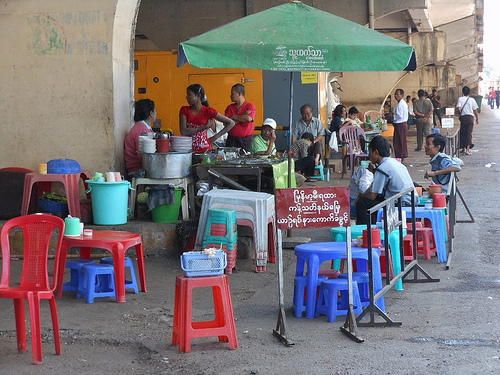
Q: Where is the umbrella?
A: On the sidewalk.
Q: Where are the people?
A: At the restaurant.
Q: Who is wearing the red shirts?
A: The wait staff.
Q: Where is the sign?
A: Next to the buildings.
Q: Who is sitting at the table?
A: Two men.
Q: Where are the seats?
A: On the sidewalk.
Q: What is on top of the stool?
A: Basket.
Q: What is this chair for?
A: Sitting.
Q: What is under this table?
A: Stools.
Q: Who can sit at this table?
A: Children.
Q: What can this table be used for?
A: Dining.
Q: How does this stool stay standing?
A: Legs.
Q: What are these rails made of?
A: Metal.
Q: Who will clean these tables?
A: Workers.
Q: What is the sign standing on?
A: Legs.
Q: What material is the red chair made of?
A: Plastic.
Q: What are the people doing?
A: Eating.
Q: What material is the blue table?
A: Plastic.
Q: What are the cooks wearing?
A: T-shirts.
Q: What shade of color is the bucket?
A: Green.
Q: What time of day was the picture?
A: Afternoon.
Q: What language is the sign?
A: Arabic.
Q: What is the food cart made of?
A: Metal.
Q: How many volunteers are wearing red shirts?
A: Three.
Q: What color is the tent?
A: Green.